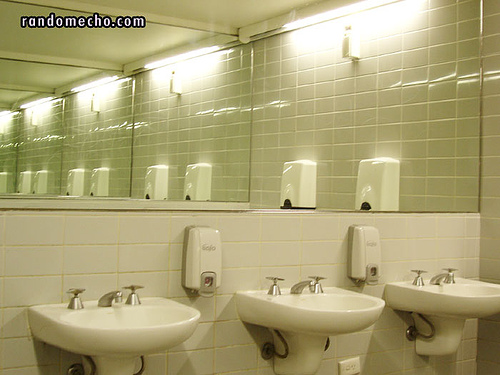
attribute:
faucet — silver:
[95, 283, 149, 307]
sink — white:
[25, 287, 209, 372]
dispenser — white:
[339, 216, 399, 293]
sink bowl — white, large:
[50, 297, 202, 342]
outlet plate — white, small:
[337, 354, 363, 374]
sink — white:
[28, 295, 201, 374]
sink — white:
[382, 274, 498, 326]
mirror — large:
[111, 36, 445, 217]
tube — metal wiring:
[134, 354, 149, 374]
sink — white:
[237, 285, 384, 373]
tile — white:
[402, 81, 429, 106]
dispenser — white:
[181, 227, 226, 300]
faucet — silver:
[395, 258, 466, 288]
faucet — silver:
[252, 261, 337, 301]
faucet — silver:
[58, 282, 161, 315]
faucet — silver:
[258, 273, 344, 298]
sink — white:
[232, 261, 388, 370]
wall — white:
[5, 198, 484, 359]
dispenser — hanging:
[342, 219, 385, 285]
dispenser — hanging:
[179, 217, 227, 298]